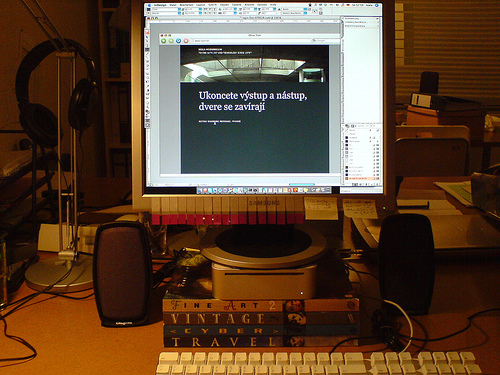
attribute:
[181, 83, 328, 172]
display — non-English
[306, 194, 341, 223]
note — sticky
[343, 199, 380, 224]
note — sticky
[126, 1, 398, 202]
computer screen — silver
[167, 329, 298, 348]
book — travel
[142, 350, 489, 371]
keyboard — white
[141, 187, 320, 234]
tabs — sticky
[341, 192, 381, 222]
note — sticky, yellow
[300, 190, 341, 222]
note — yellow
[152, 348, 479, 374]
keyboard — white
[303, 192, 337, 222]
sticky note — rectangle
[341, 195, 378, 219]
sticky note — rectangle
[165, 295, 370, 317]
book — Fine Art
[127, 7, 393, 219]
computer monitor — silver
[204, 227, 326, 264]
base — circular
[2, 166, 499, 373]
desk — computer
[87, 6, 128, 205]
bookcase — pictured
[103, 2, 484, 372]
monitor — square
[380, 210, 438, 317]
speaker — black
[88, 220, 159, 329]
speaker — black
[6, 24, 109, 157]
headphones — large, black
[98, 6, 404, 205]
monitor — on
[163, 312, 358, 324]
book — Vintage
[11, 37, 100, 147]
headphones — black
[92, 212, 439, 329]
speakers — black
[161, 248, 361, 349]
books — stacked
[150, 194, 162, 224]
paper tab — small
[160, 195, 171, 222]
paper tab — small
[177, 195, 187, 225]
paper tab — small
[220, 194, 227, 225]
paper tab — small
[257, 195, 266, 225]
paper tab — small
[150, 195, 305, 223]
paper tabs — small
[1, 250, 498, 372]
table — cluttered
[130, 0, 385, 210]
screen — open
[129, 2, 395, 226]
computer — square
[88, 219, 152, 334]
speaker — computer, left-side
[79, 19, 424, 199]
computer — black and white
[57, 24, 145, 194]
light — long, metal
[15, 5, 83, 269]
arm — metal, flexible